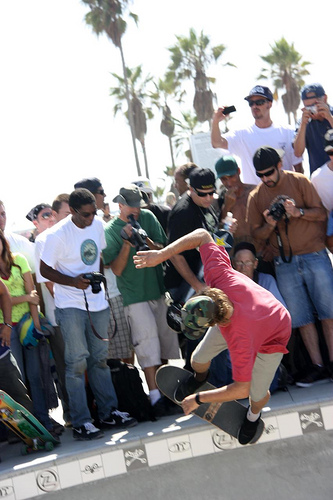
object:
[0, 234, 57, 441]
woman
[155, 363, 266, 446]
board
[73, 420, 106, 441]
shoes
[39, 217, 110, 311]
shirt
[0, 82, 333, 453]
they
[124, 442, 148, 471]
tiles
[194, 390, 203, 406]
watch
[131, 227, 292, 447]
skateboarder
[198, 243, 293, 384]
shirt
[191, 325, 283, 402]
shorts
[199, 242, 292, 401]
outfit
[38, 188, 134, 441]
spectators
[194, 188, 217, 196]
sunglasses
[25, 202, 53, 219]
bandana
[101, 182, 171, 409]
man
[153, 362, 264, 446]
skateboard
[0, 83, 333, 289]
crowd watching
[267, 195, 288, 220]
camera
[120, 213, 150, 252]
camera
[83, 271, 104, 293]
camera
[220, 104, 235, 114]
camera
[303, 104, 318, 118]
camera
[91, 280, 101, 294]
extended lens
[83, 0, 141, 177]
trees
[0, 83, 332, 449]
crowd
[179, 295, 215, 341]
camouflage hat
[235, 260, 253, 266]
glasses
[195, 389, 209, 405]
wrist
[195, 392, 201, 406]
band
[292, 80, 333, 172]
man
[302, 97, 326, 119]
face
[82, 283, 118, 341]
strap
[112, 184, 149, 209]
hat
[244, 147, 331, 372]
man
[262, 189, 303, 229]
chest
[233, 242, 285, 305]
man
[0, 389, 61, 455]
skateboard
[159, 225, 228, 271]
arm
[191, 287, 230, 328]
head